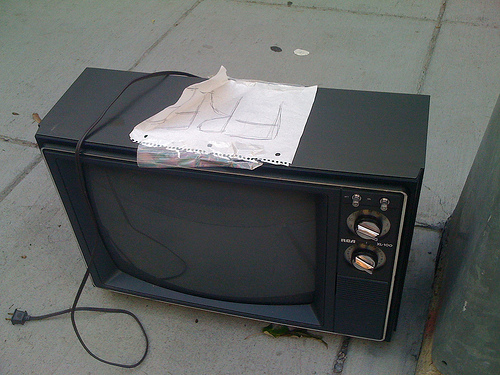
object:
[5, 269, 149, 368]
cable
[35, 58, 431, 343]
television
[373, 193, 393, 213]
tuning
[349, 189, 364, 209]
tuning knob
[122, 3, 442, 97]
tile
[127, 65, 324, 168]
paper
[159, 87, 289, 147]
writing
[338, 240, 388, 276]
knob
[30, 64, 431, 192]
frame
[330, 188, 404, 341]
control panel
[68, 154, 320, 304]
screen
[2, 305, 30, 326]
plug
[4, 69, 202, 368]
cord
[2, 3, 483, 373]
sidewalk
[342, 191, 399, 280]
controls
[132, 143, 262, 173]
tape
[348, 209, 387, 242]
knob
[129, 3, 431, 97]
concrete square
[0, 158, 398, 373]
concrete square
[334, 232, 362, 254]
writing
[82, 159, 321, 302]
glass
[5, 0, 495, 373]
ground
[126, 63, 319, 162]
sign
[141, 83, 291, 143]
free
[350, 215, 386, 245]
dial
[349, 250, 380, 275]
dial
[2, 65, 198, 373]
electrical cord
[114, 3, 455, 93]
section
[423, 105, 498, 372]
wall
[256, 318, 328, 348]
leaf